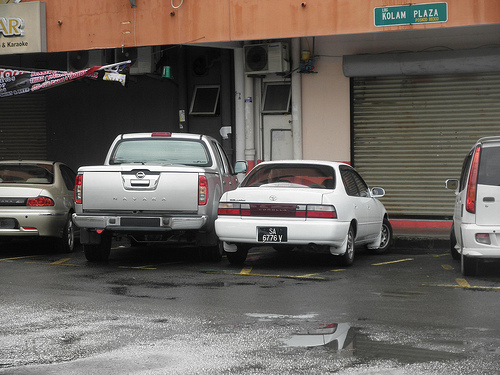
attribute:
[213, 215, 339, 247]
back bumper — at back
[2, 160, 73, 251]
sedan — gold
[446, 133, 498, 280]
suv — white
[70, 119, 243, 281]
truck — parked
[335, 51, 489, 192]
door — roll up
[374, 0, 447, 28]
sign — green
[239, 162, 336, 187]
windshield — back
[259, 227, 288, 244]
license plates — dark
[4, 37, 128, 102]
banner — twisted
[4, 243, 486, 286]
lines — yellow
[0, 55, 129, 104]
banner — twisted, red, black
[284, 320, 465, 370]
puddle — water